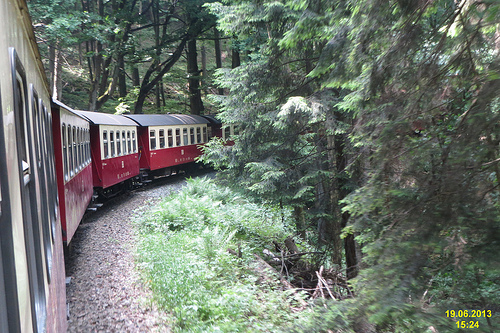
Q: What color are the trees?
A: Green.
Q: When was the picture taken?
A: Daytime.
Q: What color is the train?
A: Red.